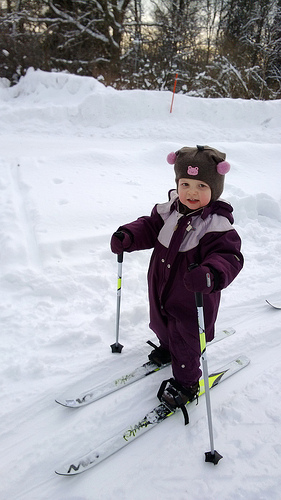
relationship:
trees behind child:
[0, 0, 280, 99] [108, 143, 246, 413]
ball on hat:
[219, 160, 230, 177] [174, 149, 220, 186]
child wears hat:
[108, 140, 247, 413] [167, 143, 229, 199]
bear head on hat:
[187, 165, 198, 175] [167, 148, 229, 188]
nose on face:
[185, 185, 197, 195] [173, 173, 214, 208]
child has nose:
[108, 143, 246, 413] [185, 185, 197, 195]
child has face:
[108, 143, 246, 413] [173, 173, 214, 208]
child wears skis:
[108, 140, 247, 413] [53, 359, 154, 475]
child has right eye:
[108, 140, 247, 413] [180, 181, 189, 187]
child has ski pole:
[108, 140, 247, 413] [192, 285, 225, 468]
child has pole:
[108, 140, 247, 413] [115, 252, 123, 347]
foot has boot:
[145, 340, 172, 368] [145, 343, 170, 366]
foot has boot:
[163, 374, 199, 408] [160, 380, 199, 408]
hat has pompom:
[165, 143, 232, 207] [215, 160, 231, 172]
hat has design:
[167, 143, 229, 199] [184, 164, 201, 177]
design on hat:
[184, 164, 201, 177] [167, 143, 229, 199]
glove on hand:
[180, 265, 212, 294] [182, 263, 214, 294]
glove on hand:
[105, 227, 127, 257] [109, 227, 130, 254]